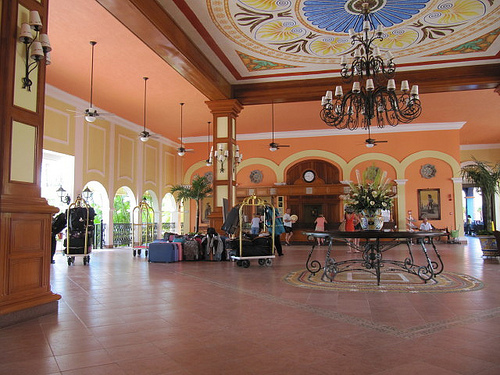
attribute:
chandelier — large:
[324, 27, 427, 134]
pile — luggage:
[144, 222, 236, 266]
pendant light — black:
[85, 40, 99, 125]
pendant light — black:
[140, 74, 152, 144]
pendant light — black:
[178, 105, 185, 159]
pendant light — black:
[203, 119, 212, 169]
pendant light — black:
[268, 100, 288, 154]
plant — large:
[343, 162, 398, 217]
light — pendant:
[285, 50, 399, 134]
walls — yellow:
[45, 91, 225, 219]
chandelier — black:
[313, 11, 425, 132]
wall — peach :
[180, 128, 464, 243]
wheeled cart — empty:
[120, 194, 161, 256]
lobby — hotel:
[36, 98, 465, 354]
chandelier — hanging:
[316, 0, 423, 134]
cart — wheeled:
[215, 192, 303, 274]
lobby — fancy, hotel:
[2, 1, 494, 368]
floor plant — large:
[459, 153, 499, 260]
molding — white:
[48, 83, 188, 156]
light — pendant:
[64, 45, 111, 125]